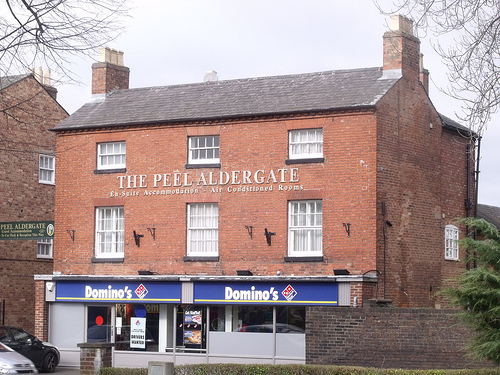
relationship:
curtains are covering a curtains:
[287, 199, 323, 256] [91, 202, 129, 264]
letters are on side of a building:
[105, 167, 313, 195] [45, 73, 472, 364]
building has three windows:
[45, 73, 472, 364] [76, 191, 336, 266]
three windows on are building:
[95, 128, 332, 173] [45, 73, 472, 364]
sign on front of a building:
[58, 272, 185, 305] [45, 73, 472, 364]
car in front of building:
[4, 328, 58, 372] [45, 73, 472, 364]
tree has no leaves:
[411, 4, 499, 305] [454, 112, 463, 121]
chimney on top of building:
[92, 43, 130, 97] [45, 73, 472, 364]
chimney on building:
[368, 13, 423, 80] [45, 73, 472, 364]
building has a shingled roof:
[45, 73, 472, 364] [60, 77, 377, 119]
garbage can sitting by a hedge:
[147, 359, 177, 374] [179, 364, 379, 374]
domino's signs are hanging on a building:
[55, 276, 339, 306] [45, 73, 472, 364]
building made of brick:
[45, 73, 472, 364] [326, 113, 375, 273]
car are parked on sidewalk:
[4, 328, 58, 372] [48, 367, 240, 374]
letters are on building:
[105, 167, 313, 195] [45, 73, 472, 364]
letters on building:
[105, 167, 313, 195] [45, 73, 472, 364]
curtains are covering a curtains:
[95, 141, 125, 171] [91, 202, 129, 264]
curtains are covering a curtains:
[184, 131, 224, 165] [91, 202, 129, 264]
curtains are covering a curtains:
[285, 121, 332, 160] [91, 202, 129, 264]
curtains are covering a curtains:
[183, 199, 227, 263] [91, 202, 129, 264]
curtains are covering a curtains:
[287, 195, 335, 261] [91, 202, 129, 264]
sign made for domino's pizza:
[58, 272, 185, 305] [55, 276, 339, 306]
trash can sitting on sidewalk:
[147, 359, 177, 374] [48, 367, 240, 374]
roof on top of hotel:
[60, 77, 377, 119] [45, 73, 472, 364]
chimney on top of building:
[368, 13, 423, 80] [45, 73, 472, 364]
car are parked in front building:
[4, 328, 58, 372] [45, 73, 472, 364]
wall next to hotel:
[304, 305, 472, 359] [45, 73, 472, 364]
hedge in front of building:
[179, 364, 379, 374] [45, 73, 472, 364]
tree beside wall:
[411, 4, 499, 305] [304, 305, 472, 359]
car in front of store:
[4, 328, 58, 372] [32, 267, 363, 355]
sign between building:
[58, 272, 185, 305] [45, 73, 472, 364]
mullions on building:
[444, 224, 460, 262] [45, 73, 472, 364]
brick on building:
[326, 113, 375, 273] [45, 73, 472, 364]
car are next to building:
[4, 328, 58, 372] [45, 73, 472, 364]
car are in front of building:
[4, 328, 58, 372] [45, 73, 472, 364]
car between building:
[4, 328, 58, 372] [45, 73, 472, 364]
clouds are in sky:
[100, 1, 339, 83] [9, 1, 490, 83]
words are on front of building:
[105, 167, 313, 195] [45, 73, 472, 364]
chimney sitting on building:
[92, 43, 130, 97] [45, 73, 472, 364]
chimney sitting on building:
[368, 13, 423, 80] [45, 73, 472, 364]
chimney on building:
[44, 80, 56, 99] [4, 69, 64, 167]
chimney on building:
[420, 54, 430, 86] [45, 73, 472, 364]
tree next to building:
[411, 4, 499, 305] [45, 73, 472, 364]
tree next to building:
[3, 1, 109, 86] [45, 73, 472, 364]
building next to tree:
[45, 73, 472, 364] [411, 4, 499, 305]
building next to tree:
[45, 73, 472, 364] [3, 1, 109, 86]